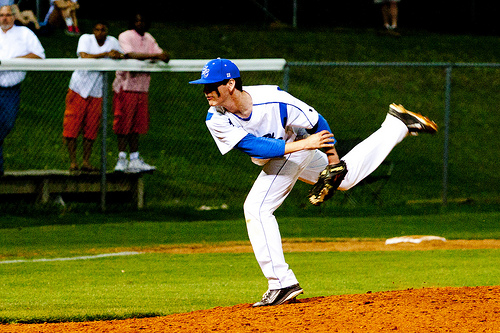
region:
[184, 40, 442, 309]
male baseball pitcher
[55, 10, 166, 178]
two men with red shorts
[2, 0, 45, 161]
older man with glasses and white shirt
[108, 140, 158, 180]
white athletic shoes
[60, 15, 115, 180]
barefoot male with white shirt and red shorts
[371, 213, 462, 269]
third base on a baseball diamond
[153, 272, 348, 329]
the pitcher's mound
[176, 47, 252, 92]
a blue baseball cap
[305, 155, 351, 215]
a baseball glove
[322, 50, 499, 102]
a chain-link fence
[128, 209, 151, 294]
part of a field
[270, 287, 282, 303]
part of a shoe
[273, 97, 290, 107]
part of a jersey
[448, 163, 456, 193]
part of a fence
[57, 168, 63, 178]
edge of a bench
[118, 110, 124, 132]
part of a short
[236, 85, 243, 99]
neck of a man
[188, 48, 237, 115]
pitcher has blue cap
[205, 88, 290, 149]
pitcher has white shirt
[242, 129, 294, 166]
pitcher has blue undershirt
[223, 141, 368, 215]
pitcher has white pants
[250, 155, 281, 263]
blue stripe on white pants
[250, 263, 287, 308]
pitcher has black shoes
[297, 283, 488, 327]
brown and clumpy dirt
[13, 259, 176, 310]
infield grass is green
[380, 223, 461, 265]
dirt covers the base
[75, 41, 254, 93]
white padding on fence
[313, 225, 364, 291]
part of a green ground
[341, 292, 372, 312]
part of a ground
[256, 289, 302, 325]
edge of a shoe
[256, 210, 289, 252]
part of a trouser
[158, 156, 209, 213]
part of a fence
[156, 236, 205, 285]
part of a field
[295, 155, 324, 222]
part of a glove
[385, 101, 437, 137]
a man's tennis shoe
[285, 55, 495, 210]
part of a green fence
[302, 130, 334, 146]
the hand of a man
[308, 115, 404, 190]
the leg of a man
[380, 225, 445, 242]
a white base covered with dirt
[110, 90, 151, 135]
a boy's red shorts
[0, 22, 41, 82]
part of a man's short sleeve white shirt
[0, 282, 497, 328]
a large dirt mound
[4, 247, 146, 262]
a long white line